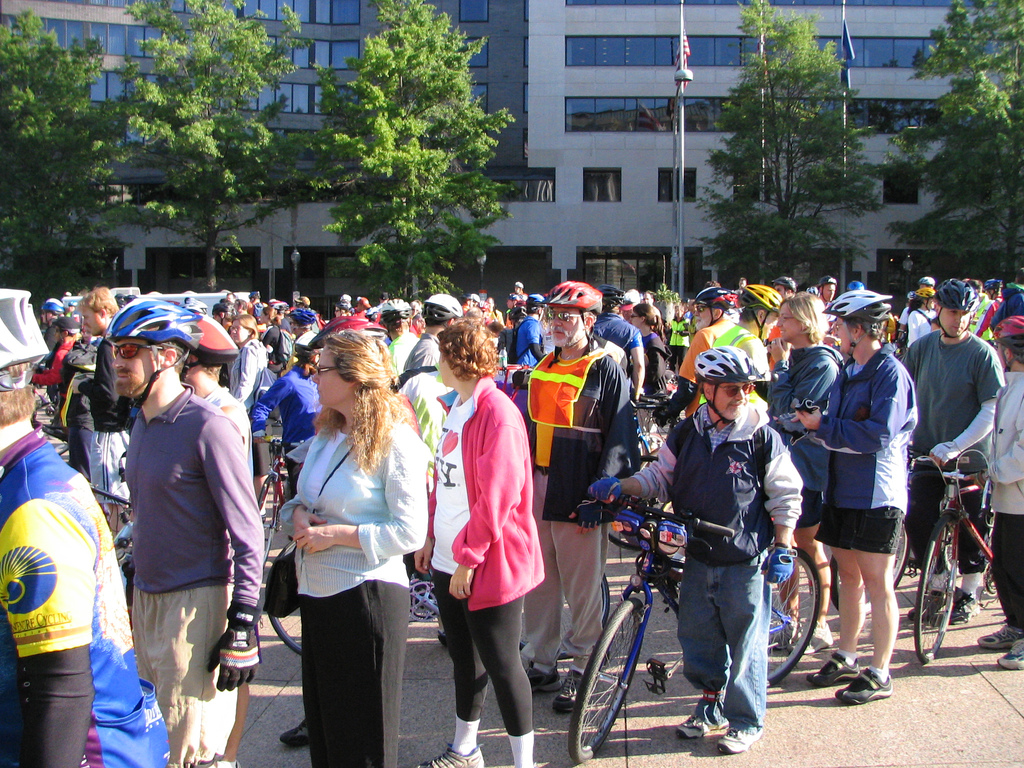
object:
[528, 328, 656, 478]
vest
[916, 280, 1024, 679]
people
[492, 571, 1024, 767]
pavement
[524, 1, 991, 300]
building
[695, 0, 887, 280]
trees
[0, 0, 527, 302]
building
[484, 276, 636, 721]
man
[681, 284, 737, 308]
helmet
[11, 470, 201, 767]
vest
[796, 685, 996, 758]
sidewalk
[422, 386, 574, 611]
shirt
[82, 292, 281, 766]
man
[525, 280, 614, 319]
helmet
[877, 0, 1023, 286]
trees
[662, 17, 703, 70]
flags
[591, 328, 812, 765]
man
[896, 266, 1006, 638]
man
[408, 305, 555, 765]
woman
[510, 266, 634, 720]
man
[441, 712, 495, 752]
socks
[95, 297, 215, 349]
helmet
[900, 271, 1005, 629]
man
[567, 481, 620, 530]
gloves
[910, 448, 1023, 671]
bicycle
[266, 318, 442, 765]
woman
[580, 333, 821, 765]
guy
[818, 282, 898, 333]
helmet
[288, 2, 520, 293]
trees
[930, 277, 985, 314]
helmet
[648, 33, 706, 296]
poles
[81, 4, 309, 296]
trees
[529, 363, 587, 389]
stripe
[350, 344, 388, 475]
hair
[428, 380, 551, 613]
coat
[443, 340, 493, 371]
hair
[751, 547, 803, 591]
gloves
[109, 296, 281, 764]
man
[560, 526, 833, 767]
bicycle